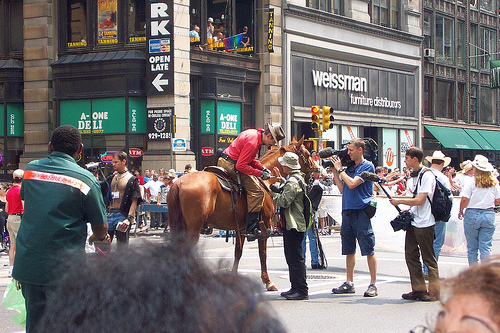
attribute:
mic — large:
[353, 160, 410, 223]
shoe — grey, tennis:
[329, 280, 355, 295]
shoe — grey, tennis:
[362, 280, 380, 297]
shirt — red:
[223, 125, 270, 174]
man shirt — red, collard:
[215, 118, 282, 193]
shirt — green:
[16, 151, 105, 284]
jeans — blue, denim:
[461, 202, 498, 268]